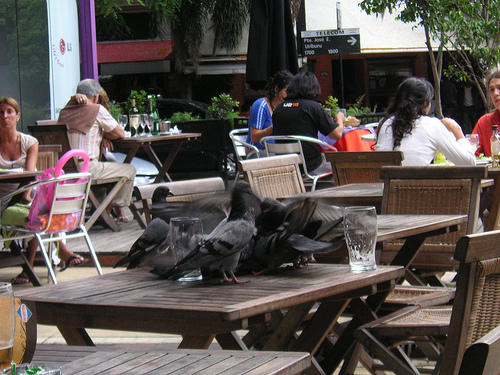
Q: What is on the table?
A: Pigeons.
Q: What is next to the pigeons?
A: Glasses.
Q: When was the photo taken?
A: Daytime.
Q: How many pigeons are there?
A: More than three.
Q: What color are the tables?
A: Brown.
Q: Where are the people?
A: Sitting.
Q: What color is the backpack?
A: Pink.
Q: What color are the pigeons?
A: Black and gray.